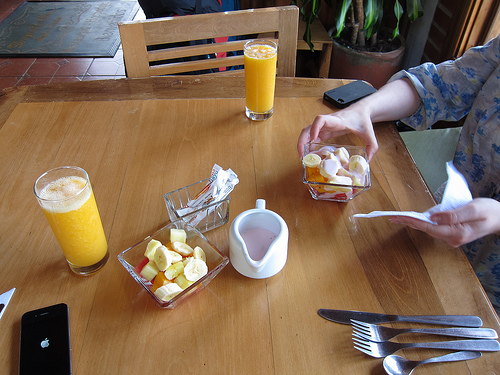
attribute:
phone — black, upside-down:
[323, 80, 378, 106]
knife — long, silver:
[317, 308, 483, 329]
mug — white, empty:
[232, 198, 290, 278]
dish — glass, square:
[163, 175, 230, 234]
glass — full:
[245, 39, 277, 121]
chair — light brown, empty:
[118, 6, 299, 82]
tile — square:
[22, 56, 95, 76]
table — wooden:
[2, 78, 500, 374]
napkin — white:
[443, 162, 469, 218]